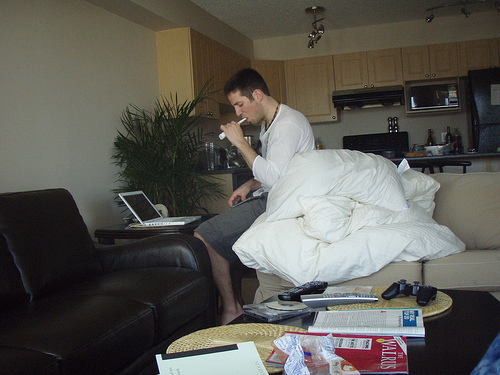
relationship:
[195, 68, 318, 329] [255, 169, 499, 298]
man sitting on arm of sofa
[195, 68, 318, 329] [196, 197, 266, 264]
man wearing shorts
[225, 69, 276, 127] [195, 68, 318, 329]
head of man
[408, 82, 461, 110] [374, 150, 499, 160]
microwave oven over counter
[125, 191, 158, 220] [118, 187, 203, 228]
screen of computer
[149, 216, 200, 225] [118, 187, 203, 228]
keyboard area on computer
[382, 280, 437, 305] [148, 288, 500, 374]
remote on table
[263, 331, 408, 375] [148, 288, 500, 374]
valrus magazine on table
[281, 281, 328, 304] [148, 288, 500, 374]
remote control on table